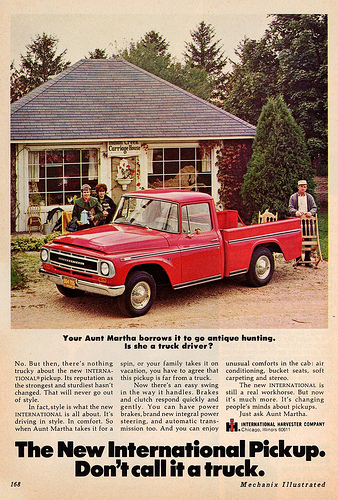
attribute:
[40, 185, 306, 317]
pickup truck — red, old, older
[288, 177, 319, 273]
man — older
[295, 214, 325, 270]
chair — an antique, wooden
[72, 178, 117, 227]
women — holding items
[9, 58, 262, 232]
antique store — for antique, small, little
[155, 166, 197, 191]
carousel horse —  horse's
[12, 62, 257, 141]
roof of house — black, gray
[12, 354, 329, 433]
two paragraphs —  Two,  text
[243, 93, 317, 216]
christmas tree — small,  an evergreen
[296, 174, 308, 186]
hat — white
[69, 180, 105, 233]
lady — grayhaired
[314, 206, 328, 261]
grass — green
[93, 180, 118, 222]
woman — holding her purchase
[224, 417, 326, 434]
logo — for International Harvester Company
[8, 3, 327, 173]
pine trees — in a line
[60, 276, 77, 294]
license plate —  The front , for license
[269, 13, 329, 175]
tree — tall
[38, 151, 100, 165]
flowering plant — pink